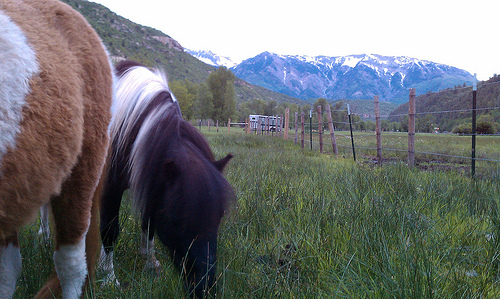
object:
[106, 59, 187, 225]
mane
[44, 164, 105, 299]
leg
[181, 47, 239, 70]
snow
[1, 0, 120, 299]
horses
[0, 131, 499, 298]
grass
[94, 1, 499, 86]
sky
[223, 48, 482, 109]
mountains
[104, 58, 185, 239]
hair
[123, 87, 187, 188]
neck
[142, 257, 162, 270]
hoof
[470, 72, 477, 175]
post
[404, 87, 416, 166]
post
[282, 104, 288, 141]
post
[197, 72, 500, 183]
fence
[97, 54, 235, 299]
animal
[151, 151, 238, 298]
head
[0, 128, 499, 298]
field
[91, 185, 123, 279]
leg